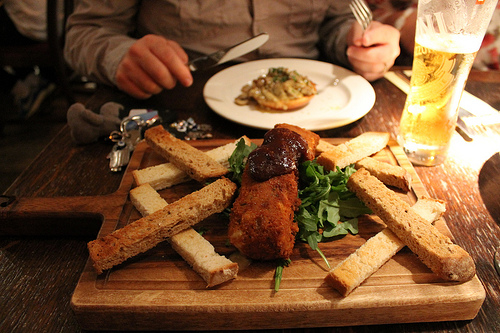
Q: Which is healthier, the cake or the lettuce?
A: The lettuce is healthier than the cake.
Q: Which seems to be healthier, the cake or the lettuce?
A: The lettuce is healthier than the cake.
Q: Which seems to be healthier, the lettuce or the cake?
A: The lettuce is healthier than the cake.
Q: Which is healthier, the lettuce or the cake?
A: The lettuce is healthier than the cake.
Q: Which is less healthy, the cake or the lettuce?
A: The cake is less healthy than the lettuce.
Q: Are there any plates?
A: Yes, there is a plate.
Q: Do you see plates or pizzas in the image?
A: Yes, there is a plate.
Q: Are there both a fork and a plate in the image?
A: Yes, there are both a plate and a fork.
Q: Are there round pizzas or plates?
A: Yes, there is a round plate.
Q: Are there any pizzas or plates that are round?
A: Yes, the plate is round.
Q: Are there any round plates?
A: Yes, there is a round plate.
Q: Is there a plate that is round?
A: Yes, there is a plate that is round.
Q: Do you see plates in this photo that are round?
A: Yes, there is a plate that is round.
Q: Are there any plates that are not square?
A: Yes, there is a round plate.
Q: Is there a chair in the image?
A: No, there are no chairs.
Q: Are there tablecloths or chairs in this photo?
A: No, there are no chairs or tablecloths.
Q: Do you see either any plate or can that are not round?
A: No, there is a plate but it is round.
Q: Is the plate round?
A: Yes, the plate is round.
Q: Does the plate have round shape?
A: Yes, the plate is round.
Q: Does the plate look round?
A: Yes, the plate is round.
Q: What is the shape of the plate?
A: The plate is round.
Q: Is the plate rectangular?
A: No, the plate is round.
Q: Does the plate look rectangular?
A: No, the plate is round.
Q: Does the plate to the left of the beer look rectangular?
A: No, the plate is round.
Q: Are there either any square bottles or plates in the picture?
A: No, there is a plate but it is round.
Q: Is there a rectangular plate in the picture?
A: No, there is a plate but it is round.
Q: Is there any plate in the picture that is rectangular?
A: No, there is a plate but it is round.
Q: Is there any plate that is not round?
A: No, there is a plate but it is round.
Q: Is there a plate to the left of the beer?
A: Yes, there is a plate to the left of the beer.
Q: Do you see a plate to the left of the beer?
A: Yes, there is a plate to the left of the beer.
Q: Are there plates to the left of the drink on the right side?
A: Yes, there is a plate to the left of the beer.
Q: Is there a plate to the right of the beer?
A: No, the plate is to the left of the beer.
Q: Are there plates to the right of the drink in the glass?
A: No, the plate is to the left of the beer.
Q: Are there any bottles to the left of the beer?
A: No, there is a plate to the left of the beer.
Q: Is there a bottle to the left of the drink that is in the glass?
A: No, there is a plate to the left of the beer.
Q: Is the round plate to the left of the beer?
A: Yes, the plate is to the left of the beer.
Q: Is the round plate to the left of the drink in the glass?
A: Yes, the plate is to the left of the beer.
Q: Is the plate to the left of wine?
A: No, the plate is to the left of the beer.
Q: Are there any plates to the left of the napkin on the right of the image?
A: Yes, there is a plate to the left of the napkin.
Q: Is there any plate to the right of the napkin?
A: No, the plate is to the left of the napkin.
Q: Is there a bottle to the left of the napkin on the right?
A: No, there is a plate to the left of the napkin.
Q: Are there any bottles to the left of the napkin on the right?
A: No, there is a plate to the left of the napkin.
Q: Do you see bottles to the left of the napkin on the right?
A: No, there is a plate to the left of the napkin.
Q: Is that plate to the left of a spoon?
A: No, the plate is to the left of the napkin.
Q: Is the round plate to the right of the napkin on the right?
A: No, the plate is to the left of the napkin.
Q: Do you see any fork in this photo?
A: Yes, there is a fork.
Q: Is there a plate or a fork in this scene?
A: Yes, there is a fork.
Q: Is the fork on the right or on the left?
A: The fork is on the right of the image.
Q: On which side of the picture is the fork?
A: The fork is on the right of the image.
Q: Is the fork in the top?
A: Yes, the fork is in the top of the image.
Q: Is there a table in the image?
A: Yes, there is a table.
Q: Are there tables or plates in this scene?
A: Yes, there is a table.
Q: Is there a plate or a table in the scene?
A: Yes, there is a table.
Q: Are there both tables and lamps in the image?
A: No, there is a table but no lamps.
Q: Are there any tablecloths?
A: No, there are no tablecloths.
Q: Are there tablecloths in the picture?
A: No, there are no tablecloths.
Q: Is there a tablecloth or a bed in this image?
A: No, there are no tablecloths or beds.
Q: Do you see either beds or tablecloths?
A: No, there are no tablecloths or beds.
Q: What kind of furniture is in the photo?
A: The furniture is a table.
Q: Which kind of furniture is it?
A: The piece of furniture is a table.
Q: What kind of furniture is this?
A: This is a table.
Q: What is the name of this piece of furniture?
A: This is a table.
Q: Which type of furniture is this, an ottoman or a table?
A: This is a table.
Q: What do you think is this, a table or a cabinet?
A: This is a table.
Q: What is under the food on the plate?
A: The table is under the food.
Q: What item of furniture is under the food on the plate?
A: The piece of furniture is a table.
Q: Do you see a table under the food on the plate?
A: Yes, there is a table under the food.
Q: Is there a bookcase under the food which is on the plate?
A: No, there is a table under the food.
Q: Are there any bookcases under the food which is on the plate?
A: No, there is a table under the food.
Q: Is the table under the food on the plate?
A: Yes, the table is under the food.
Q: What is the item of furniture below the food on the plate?
A: The piece of furniture is a table.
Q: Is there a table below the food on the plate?
A: Yes, there is a table below the food.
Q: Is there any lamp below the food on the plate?
A: No, there is a table below the food.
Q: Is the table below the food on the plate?
A: Yes, the table is below the food.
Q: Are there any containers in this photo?
A: No, there are no containers.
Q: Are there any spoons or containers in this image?
A: No, there are no containers or spoons.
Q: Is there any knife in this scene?
A: Yes, there is a knife.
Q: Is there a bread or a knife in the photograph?
A: Yes, there is a knife.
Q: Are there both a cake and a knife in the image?
A: Yes, there are both a knife and a cake.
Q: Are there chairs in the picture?
A: No, there are no chairs.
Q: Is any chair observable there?
A: No, there are no chairs.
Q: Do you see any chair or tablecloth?
A: No, there are no chairs or tablecloths.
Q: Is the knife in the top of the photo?
A: Yes, the knife is in the top of the image.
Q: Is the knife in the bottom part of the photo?
A: No, the knife is in the top of the image.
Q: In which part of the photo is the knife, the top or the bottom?
A: The knife is in the top of the image.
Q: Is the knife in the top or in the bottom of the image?
A: The knife is in the top of the image.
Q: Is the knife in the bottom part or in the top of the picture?
A: The knife is in the top of the image.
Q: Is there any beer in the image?
A: Yes, there is beer.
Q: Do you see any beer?
A: Yes, there is beer.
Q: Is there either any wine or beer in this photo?
A: Yes, there is beer.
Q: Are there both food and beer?
A: Yes, there are both beer and food.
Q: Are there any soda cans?
A: No, there are no soda cans.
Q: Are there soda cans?
A: No, there are no soda cans.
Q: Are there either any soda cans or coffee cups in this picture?
A: No, there are no soda cans or coffee cups.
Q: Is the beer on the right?
A: Yes, the beer is on the right of the image.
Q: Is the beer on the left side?
A: No, the beer is on the right of the image.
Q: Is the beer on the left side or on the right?
A: The beer is on the right of the image.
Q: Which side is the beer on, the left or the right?
A: The beer is on the right of the image.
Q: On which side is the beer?
A: The beer is on the right of the image.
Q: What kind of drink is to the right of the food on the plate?
A: The drink is beer.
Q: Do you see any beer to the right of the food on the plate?
A: Yes, there is beer to the right of the food.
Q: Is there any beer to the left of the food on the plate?
A: No, the beer is to the right of the food.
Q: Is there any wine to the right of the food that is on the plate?
A: No, there is beer to the right of the food.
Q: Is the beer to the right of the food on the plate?
A: Yes, the beer is to the right of the food.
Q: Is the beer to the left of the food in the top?
A: No, the beer is to the right of the food.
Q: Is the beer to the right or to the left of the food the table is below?
A: The beer is to the right of the food.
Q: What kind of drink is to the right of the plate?
A: The drink is beer.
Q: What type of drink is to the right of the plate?
A: The drink is beer.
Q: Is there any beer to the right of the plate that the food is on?
A: Yes, there is beer to the right of the plate.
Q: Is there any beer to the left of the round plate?
A: No, the beer is to the right of the plate.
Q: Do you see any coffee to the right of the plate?
A: No, there is beer to the right of the plate.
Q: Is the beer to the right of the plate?
A: Yes, the beer is to the right of the plate.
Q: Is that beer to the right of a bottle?
A: No, the beer is to the right of the plate.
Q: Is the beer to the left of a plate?
A: No, the beer is to the right of a plate.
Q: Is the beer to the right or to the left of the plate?
A: The beer is to the right of the plate.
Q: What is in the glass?
A: The beer is in the glass.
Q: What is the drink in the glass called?
A: The drink is beer.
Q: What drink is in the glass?
A: The drink is beer.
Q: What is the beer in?
A: The beer is in the glass.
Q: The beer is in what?
A: The beer is in the glass.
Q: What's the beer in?
A: The beer is in the glass.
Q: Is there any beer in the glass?
A: Yes, there is beer in the glass.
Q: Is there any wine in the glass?
A: No, there is beer in the glass.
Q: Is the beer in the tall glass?
A: Yes, the beer is in the glass.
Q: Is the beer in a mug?
A: No, the beer is in the glass.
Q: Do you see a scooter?
A: No, there are no scooters.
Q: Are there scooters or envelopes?
A: No, there are no scooters or envelopes.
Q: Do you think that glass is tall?
A: Yes, the glass is tall.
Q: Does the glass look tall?
A: Yes, the glass is tall.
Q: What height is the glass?
A: The glass is tall.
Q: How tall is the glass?
A: The glass is tall.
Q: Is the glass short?
A: No, the glass is tall.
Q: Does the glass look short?
A: No, the glass is tall.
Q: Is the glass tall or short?
A: The glass is tall.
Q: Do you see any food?
A: Yes, there is food.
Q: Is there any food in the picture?
A: Yes, there is food.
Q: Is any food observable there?
A: Yes, there is food.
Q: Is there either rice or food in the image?
A: Yes, there is food.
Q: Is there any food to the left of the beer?
A: Yes, there is food to the left of the beer.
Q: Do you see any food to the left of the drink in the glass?
A: Yes, there is food to the left of the beer.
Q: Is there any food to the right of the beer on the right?
A: No, the food is to the left of the beer.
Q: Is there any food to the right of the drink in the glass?
A: No, the food is to the left of the beer.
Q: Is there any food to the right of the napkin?
A: No, the food is to the left of the napkin.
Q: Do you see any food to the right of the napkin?
A: No, the food is to the left of the napkin.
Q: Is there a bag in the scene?
A: No, there are no bags.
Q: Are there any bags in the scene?
A: No, there are no bags.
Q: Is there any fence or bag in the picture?
A: No, there are no bags or fences.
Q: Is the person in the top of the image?
A: Yes, the person is in the top of the image.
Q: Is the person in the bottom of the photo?
A: No, the person is in the top of the image.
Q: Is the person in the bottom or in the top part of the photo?
A: The person is in the top of the image.